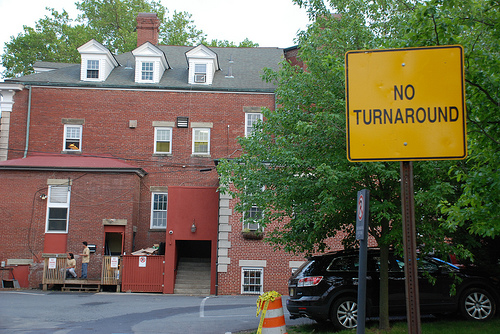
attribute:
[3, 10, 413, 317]
building — red, brick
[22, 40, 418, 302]
building — brick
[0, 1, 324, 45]
sky — overcast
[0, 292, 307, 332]
pavement — black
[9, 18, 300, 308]
building — brick, large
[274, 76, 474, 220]
tree — large, green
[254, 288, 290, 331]
cone — orange, white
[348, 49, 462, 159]
sign — orange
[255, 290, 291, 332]
cone — orange, white, striped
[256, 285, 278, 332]
caution tape — yellow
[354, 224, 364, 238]
writing — red, white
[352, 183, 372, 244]
sign — no parking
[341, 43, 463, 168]
sign — yellow, gray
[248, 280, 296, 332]
barrel — orange, black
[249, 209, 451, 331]
suv — black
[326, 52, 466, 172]
sign — yellow, black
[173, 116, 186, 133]
light — black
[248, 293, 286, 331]
cone — orange, white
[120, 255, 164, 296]
dumpster — red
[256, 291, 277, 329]
tape — yellow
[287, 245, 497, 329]
car — black